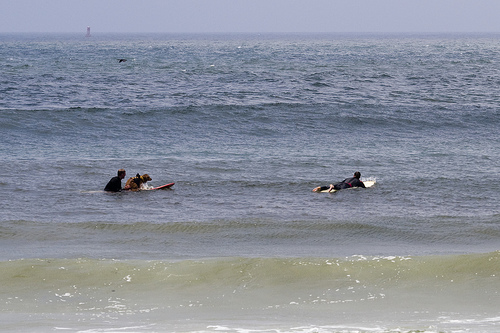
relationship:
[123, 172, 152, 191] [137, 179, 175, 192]
dog on surfboard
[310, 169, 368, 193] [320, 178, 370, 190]
man has wetsuit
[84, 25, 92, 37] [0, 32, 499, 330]
floater in water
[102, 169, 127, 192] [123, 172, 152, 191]
man teaching dog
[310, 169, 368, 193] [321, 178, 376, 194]
man on surfboard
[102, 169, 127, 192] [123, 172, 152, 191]
man with dog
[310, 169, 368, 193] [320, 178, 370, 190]
man in wetsuit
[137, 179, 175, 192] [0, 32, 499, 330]
surfboard in water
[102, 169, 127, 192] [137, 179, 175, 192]
man on surfboard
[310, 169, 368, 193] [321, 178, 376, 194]
man lying on surfboard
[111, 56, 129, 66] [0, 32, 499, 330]
bird flying over water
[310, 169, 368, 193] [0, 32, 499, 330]
man in water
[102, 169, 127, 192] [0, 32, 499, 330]
man in water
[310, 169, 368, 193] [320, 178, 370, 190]
man wearing wetsuit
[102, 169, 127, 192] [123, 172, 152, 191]
man pushing dog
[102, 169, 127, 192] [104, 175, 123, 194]
man wearing black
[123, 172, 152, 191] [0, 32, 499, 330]
dog in water